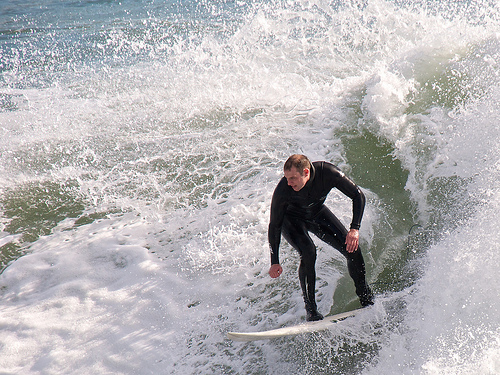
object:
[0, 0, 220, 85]
blue water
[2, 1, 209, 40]
section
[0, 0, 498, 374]
wave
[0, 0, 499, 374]
ocean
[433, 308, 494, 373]
white